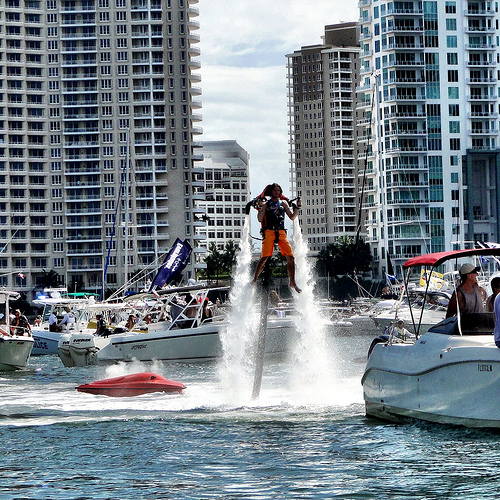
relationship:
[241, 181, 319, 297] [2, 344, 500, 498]
skier in water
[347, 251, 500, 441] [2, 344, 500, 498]
boat in water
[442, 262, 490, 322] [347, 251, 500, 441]
man steering boat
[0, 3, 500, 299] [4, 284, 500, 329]
buildings along shore line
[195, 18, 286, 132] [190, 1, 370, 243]
clouds in sky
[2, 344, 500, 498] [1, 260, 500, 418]
water by boats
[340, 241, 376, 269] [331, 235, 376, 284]
leaves on a tree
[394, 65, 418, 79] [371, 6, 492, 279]
window of a building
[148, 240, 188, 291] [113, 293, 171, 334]
banner on a boat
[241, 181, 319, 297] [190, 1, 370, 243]
skier in sky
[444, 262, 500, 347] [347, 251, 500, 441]
people on boat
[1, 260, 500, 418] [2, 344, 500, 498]
boats on water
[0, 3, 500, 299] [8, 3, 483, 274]
buildings have windows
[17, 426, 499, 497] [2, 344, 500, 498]
ripples on water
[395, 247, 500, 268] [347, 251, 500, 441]
hood on a boat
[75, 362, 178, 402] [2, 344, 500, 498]
jet ski on water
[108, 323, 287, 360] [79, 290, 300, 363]
stripes on boat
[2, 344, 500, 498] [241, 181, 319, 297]
water below skier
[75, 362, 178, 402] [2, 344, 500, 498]
jet ski in water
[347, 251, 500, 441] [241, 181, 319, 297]
boat next to skier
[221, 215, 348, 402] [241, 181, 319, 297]
water coming off skier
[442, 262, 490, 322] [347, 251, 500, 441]
man inside boat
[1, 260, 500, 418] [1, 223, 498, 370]
boats in background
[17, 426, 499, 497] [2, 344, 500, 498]
ripples in water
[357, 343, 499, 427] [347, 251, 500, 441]
side of boat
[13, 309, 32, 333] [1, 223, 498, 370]
person in background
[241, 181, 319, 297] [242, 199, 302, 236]
skier using jet pack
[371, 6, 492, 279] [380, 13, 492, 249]
building has balconies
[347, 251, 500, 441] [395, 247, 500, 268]
boat has hood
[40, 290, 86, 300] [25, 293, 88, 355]
roof of boat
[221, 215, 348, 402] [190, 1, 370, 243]
water in sky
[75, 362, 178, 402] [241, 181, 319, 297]
jet ski next to skier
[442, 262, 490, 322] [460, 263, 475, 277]
man with hat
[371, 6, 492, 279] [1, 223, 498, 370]
building in background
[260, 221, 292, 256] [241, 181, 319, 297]
shorts on skier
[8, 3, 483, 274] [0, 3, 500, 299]
windows on buildings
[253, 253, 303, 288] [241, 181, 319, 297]
legs of skier